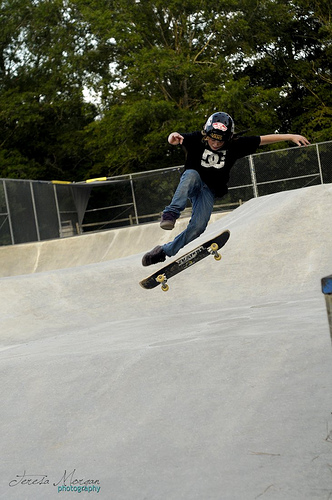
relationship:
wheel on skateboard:
[210, 240, 219, 252] [139, 224, 235, 288]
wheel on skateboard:
[212, 253, 221, 260] [139, 224, 235, 288]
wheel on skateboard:
[154, 272, 165, 281] [139, 224, 235, 288]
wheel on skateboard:
[162, 284, 169, 291] [139, 224, 235, 288]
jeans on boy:
[159, 167, 212, 257] [140, 110, 308, 266]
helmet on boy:
[202, 110, 234, 141] [140, 110, 308, 266]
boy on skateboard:
[140, 110, 308, 266] [140, 229, 232, 291]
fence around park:
[0, 139, 331, 247] [0, 182, 331, 499]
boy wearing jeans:
[140, 110, 308, 266] [141, 167, 214, 259]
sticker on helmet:
[211, 120, 228, 131] [198, 110, 234, 146]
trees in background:
[2, 1, 330, 182] [2, 3, 328, 356]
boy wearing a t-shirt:
[140, 110, 308, 266] [179, 132, 261, 199]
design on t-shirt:
[199, 149, 227, 169] [179, 132, 261, 199]